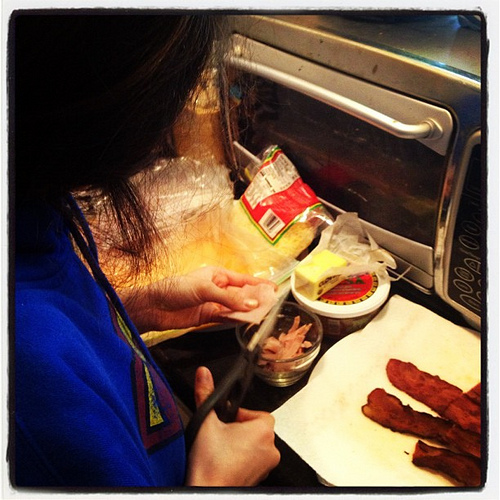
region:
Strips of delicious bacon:
[356, 345, 483, 485]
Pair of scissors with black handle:
[184, 268, 302, 425]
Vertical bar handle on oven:
[223, 31, 450, 145]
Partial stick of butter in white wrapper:
[285, 210, 391, 303]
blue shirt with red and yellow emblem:
[5, 210, 218, 491]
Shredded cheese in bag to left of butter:
[226, 145, 334, 262]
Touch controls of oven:
[438, 122, 485, 327]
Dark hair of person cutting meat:
[12, 10, 251, 253]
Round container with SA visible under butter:
[292, 251, 395, 336]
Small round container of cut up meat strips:
[240, 292, 329, 390]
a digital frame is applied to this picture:
[3, 0, 494, 496]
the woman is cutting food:
[10, 9, 307, 487]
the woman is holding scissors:
[160, 260, 324, 495]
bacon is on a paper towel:
[365, 334, 495, 498]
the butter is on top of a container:
[283, 242, 383, 315]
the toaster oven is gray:
[218, 16, 496, 341]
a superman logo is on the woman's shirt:
[78, 274, 203, 456]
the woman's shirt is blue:
[10, 209, 224, 496]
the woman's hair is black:
[15, 9, 230, 253]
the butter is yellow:
[286, 240, 357, 307]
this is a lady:
[23, 49, 156, 411]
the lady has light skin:
[213, 438, 238, 440]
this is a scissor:
[238, 330, 255, 390]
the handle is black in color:
[213, 380, 228, 399]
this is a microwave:
[308, 65, 453, 200]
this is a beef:
[386, 361, 466, 463]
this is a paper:
[303, 398, 343, 452]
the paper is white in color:
[298, 392, 343, 458]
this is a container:
[341, 280, 371, 317]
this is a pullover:
[54, 285, 166, 491]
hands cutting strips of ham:
[114, 262, 304, 489]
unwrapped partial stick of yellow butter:
[292, 208, 401, 298]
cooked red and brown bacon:
[358, 346, 490, 492]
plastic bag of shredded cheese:
[233, 141, 331, 268]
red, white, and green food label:
[239, 142, 326, 247]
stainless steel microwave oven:
[214, 10, 486, 334]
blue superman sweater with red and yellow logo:
[8, 192, 191, 497]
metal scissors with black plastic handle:
[187, 287, 295, 428]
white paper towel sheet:
[267, 288, 494, 493]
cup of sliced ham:
[238, 298, 325, 388]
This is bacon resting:
[367, 340, 479, 497]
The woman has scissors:
[177, 251, 318, 466]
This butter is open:
[282, 225, 392, 330]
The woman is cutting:
[195, 245, 366, 355]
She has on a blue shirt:
[11, 235, 242, 485]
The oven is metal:
[216, 25, 493, 321]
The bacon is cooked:
[363, 335, 488, 485]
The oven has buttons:
[443, 203, 483, 343]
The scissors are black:
[190, 332, 318, 457]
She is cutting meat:
[214, 244, 324, 386]